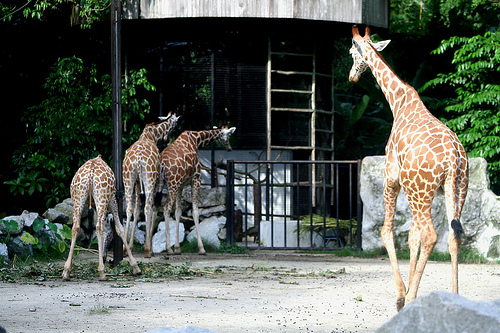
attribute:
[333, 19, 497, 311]
giraffe — tall, brown, spotted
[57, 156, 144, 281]
giraffe — spotted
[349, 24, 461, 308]
giraffe — spotted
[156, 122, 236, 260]
giraffes — brown, spotted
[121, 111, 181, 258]
giraffes — brown, spotted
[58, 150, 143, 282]
giraffes — brown, spotted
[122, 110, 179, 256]
giraffe — one, spotted, brown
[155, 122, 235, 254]
giraffe — spotted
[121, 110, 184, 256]
tall giraffe — brown, spotted